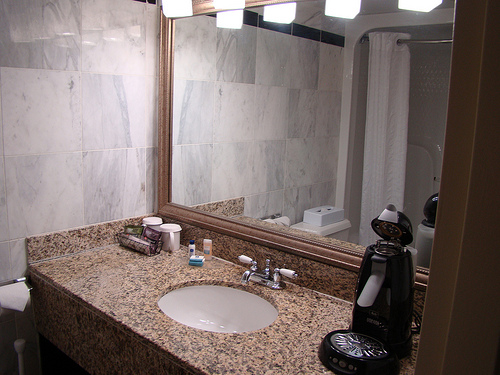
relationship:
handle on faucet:
[271, 268, 300, 287] [235, 253, 299, 293]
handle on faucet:
[235, 254, 260, 275] [235, 253, 299, 293]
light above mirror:
[212, 9, 244, 31] [173, 0, 457, 271]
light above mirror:
[261, 5, 296, 27] [173, 0, 457, 271]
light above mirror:
[325, 0, 363, 20] [173, 0, 457, 271]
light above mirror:
[399, 0, 442, 14] [173, 0, 457, 271]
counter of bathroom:
[24, 217, 422, 374] [1, 0, 499, 373]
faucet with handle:
[235, 253, 299, 293] [271, 268, 300, 287]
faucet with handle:
[235, 253, 299, 293] [235, 254, 260, 275]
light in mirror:
[212, 9, 244, 31] [173, 0, 457, 271]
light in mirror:
[261, 5, 296, 27] [173, 0, 457, 271]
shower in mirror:
[354, 26, 446, 262] [173, 0, 457, 271]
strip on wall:
[243, 11, 349, 46] [182, 19, 354, 214]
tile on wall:
[85, 74, 145, 151] [2, 0, 155, 218]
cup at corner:
[159, 223, 184, 251] [157, 230, 163, 244]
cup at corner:
[143, 217, 160, 230] [157, 230, 163, 244]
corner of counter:
[157, 230, 163, 244] [24, 217, 422, 374]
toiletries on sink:
[185, 238, 212, 269] [152, 278, 280, 336]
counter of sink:
[24, 217, 422, 374] [152, 278, 280, 336]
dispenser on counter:
[317, 202, 418, 374] [24, 217, 422, 374]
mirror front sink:
[173, 0, 457, 271] [152, 278, 280, 336]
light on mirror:
[212, 9, 244, 31] [173, 0, 457, 271]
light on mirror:
[261, 5, 296, 27] [173, 0, 457, 271]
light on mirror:
[325, 0, 363, 20] [173, 0, 457, 271]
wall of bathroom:
[2, 0, 155, 218] [1, 0, 499, 373]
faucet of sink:
[235, 253, 299, 293] [152, 278, 280, 336]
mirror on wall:
[173, 0, 457, 271] [2, 0, 155, 218]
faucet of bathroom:
[235, 253, 299, 293] [1, 0, 499, 373]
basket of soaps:
[116, 225, 166, 255] [127, 227, 161, 244]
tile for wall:
[85, 74, 145, 151] [2, 0, 155, 218]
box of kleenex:
[304, 205, 345, 224] [319, 208, 328, 213]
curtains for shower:
[356, 33, 410, 247] [354, 26, 446, 262]